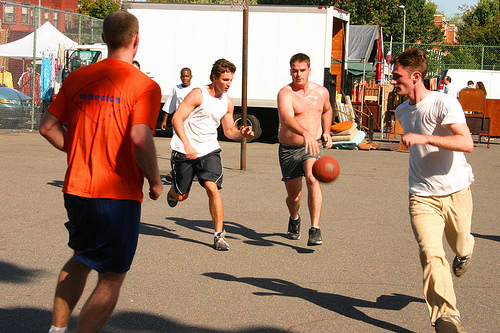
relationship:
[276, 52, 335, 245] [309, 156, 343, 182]
man dribbling basketball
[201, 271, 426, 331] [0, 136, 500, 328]
shadow on ground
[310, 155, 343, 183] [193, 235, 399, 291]
ball above ground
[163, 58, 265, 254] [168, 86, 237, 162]
man wearing vest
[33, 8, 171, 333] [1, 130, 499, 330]
man in court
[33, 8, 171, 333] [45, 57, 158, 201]
man wearing shirt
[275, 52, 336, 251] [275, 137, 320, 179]
man wearing shorts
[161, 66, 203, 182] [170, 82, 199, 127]
dark man wearing shirt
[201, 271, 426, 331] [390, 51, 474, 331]
shadow of a man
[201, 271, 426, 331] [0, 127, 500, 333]
shadow on concrete floor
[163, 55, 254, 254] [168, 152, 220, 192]
man wearing shorts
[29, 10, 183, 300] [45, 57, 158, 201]
man wearing shirt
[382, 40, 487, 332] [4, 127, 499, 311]
man running on concrete floor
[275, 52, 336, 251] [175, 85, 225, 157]
man wearing tank top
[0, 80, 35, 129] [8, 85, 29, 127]
car has front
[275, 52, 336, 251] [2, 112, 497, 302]
man on court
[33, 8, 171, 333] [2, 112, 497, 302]
man on court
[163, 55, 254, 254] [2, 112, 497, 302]
man on court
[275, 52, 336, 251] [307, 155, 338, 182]
man bouncing ball